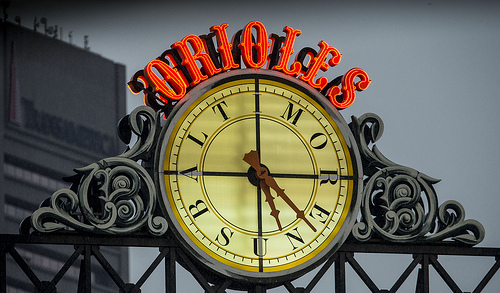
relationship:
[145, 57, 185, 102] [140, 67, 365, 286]
letter above clock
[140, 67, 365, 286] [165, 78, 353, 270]
clock has face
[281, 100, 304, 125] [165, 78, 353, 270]
letter on face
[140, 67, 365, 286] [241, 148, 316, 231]
clock has hand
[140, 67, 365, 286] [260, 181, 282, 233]
clock has hand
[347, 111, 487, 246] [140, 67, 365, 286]
scrollwork side of clock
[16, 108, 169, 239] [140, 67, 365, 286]
scrollwork side of clock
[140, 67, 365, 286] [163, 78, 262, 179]
clock has quarter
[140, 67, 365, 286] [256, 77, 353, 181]
clock has quarter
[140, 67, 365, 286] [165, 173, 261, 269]
clock has quarter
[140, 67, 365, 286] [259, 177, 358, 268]
clock has quarter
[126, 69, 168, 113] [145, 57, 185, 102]
letter behind letter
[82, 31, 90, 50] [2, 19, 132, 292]
item on top of building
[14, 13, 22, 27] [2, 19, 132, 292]
item on top of building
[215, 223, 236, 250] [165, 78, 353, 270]
letter on face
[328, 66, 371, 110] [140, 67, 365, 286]
letter above clock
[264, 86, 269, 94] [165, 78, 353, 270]
tick on face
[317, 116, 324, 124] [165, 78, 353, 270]
tick on face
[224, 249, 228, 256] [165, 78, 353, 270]
tick on face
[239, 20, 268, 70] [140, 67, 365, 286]
letter above clock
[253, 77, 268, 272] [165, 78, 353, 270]
line on face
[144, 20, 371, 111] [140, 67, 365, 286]
name above clock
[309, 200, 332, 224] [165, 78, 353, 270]
letter on face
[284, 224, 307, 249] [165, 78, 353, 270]
letter on face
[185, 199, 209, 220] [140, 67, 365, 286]
letter on clock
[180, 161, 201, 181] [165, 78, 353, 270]
letter on face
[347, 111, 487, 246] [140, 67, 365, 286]
scrollwork right of clock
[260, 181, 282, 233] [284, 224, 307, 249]
hand points at letter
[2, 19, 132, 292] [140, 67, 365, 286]
building behind clock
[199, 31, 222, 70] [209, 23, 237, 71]
letter behind letter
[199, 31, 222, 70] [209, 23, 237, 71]
letter duplicates letter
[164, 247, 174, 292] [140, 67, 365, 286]
post supports clock